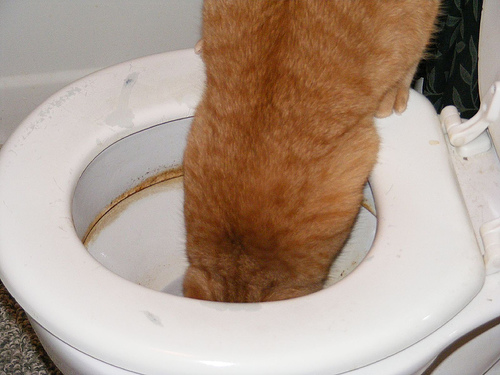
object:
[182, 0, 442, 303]
cat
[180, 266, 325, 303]
head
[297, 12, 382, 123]
striped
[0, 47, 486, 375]
seat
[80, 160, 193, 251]
stain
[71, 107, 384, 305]
toilet bowl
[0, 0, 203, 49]
side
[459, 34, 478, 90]
leaves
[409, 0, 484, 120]
curtain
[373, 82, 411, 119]
foot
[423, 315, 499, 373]
outside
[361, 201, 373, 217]
ring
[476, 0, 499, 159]
lid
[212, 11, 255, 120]
stripes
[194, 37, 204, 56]
paw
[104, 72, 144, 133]
scoff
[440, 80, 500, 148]
hinge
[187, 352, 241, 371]
light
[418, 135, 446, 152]
dirt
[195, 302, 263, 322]
peeling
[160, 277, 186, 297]
water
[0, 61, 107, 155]
molding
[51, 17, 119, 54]
white paint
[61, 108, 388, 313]
mark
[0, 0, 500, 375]
room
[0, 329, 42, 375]
floor